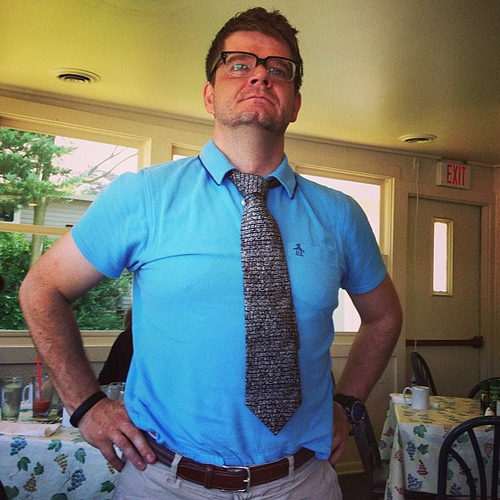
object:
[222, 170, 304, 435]
tie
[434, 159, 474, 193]
sign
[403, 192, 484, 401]
door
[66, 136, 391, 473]
blue shirt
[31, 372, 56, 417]
glass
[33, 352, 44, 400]
straw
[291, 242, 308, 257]
logo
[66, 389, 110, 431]
band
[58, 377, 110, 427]
wrist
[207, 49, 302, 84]
glasses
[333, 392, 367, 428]
watch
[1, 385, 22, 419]
water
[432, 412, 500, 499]
chairs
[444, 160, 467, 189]
exit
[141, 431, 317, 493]
belt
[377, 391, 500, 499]
tablecloth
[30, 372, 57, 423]
drink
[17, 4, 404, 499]
man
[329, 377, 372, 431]
wrist